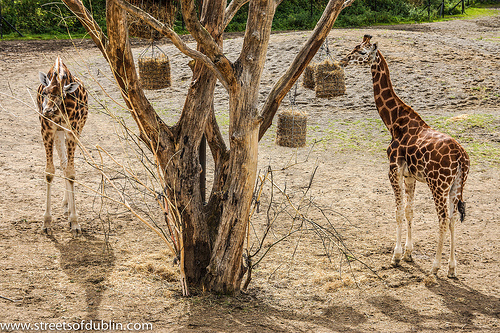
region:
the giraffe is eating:
[305, 27, 395, 133]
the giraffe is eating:
[16, 50, 141, 189]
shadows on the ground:
[4, 193, 423, 332]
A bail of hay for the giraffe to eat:
[315, 60, 346, 98]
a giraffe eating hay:
[338, 35, 470, 280]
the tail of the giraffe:
[458, 153, 465, 221]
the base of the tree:
[66, 5, 362, 299]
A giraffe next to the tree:
[33, 58, 89, 233]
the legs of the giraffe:
[39, 124, 84, 232]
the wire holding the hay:
[143, 32, 164, 57]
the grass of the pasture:
[10, 250, 156, 325]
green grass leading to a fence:
[356, 2, 496, 14]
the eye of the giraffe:
[358, 49, 367, 54]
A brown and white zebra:
[351, 42, 452, 287]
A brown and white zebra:
[20, 49, 85, 241]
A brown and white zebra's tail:
[452, 144, 470, 215]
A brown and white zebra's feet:
[435, 216, 442, 276]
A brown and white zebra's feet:
[391, 167, 404, 269]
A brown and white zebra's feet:
[405, 178, 427, 269]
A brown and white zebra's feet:
[450, 189, 459, 281]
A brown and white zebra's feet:
[36, 130, 53, 250]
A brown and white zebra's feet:
[56, 124, 92, 286]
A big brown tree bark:
[142, 1, 241, 294]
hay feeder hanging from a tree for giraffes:
[268, 80, 308, 152]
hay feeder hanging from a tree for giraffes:
[135, 20, 170, 91]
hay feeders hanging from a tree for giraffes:
[299, 26, 349, 104]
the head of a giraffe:
[336, 27, 383, 74]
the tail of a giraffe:
[453, 156, 470, 225]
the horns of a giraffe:
[359, 28, 374, 48]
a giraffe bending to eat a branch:
[30, 57, 92, 239]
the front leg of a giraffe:
[384, 154, 420, 269]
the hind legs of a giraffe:
[421, 157, 463, 285]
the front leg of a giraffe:
[36, 128, 59, 234]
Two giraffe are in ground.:
[31, 60, 470, 230]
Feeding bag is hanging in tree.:
[128, 34, 366, 190]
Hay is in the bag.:
[277, 31, 351, 152]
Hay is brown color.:
[272, 49, 342, 149]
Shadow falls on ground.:
[8, 189, 488, 331]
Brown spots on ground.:
[367, 78, 433, 155]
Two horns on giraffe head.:
[34, 70, 73, 95]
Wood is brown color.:
[140, 57, 260, 236]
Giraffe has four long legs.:
[338, 160, 491, 300]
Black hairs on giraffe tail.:
[444, 193, 475, 225]